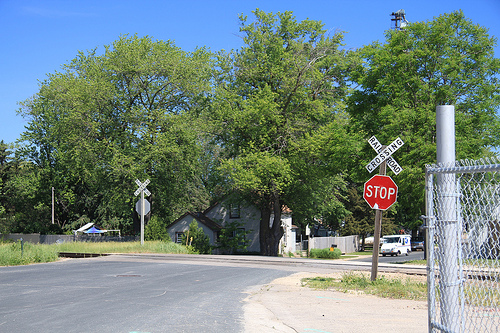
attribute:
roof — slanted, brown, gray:
[190, 206, 226, 234]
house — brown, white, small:
[169, 197, 301, 262]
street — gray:
[34, 256, 255, 331]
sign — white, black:
[361, 130, 412, 180]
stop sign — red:
[366, 173, 402, 212]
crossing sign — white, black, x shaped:
[126, 174, 157, 200]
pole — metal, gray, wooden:
[373, 160, 382, 293]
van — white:
[377, 232, 415, 260]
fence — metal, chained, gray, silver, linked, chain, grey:
[427, 166, 490, 332]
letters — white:
[367, 183, 399, 197]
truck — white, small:
[373, 232, 418, 258]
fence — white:
[69, 232, 139, 250]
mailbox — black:
[329, 243, 344, 250]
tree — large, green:
[232, 67, 312, 259]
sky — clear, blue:
[10, 3, 397, 48]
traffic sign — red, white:
[346, 174, 409, 222]